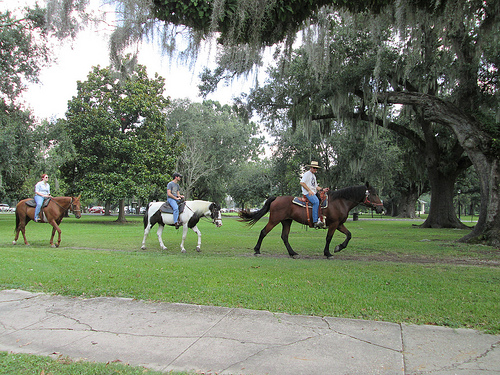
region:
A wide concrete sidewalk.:
[52, 288, 386, 368]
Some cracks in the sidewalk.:
[298, 302, 486, 369]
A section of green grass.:
[152, 248, 442, 308]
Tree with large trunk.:
[388, 46, 486, 230]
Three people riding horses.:
[11, 106, 413, 268]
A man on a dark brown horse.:
[247, 142, 389, 267]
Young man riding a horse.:
[140, 155, 223, 245]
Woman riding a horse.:
[10, 157, 87, 242]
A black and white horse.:
[127, 185, 237, 253]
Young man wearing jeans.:
[163, 169, 195, 249]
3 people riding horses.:
[11, 157, 388, 261]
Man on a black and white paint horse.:
[138, 169, 224, 254]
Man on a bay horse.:
[237, 158, 388, 260]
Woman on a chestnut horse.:
[11, 168, 84, 247]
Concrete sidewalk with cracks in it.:
[1, 287, 498, 374]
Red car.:
[87, 201, 108, 215]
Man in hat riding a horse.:
[237, 160, 387, 260]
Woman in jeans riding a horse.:
[12, 166, 85, 249]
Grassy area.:
[0, 212, 498, 332]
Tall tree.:
[58, 54, 179, 219]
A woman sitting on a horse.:
[26, 170, 56, 225]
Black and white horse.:
[137, 200, 223, 250]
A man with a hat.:
[296, 151, 334, 228]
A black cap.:
[163, 168, 187, 179]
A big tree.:
[74, 55, 166, 228]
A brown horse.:
[8, 192, 88, 248]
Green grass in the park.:
[236, 258, 358, 304]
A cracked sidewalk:
[153, 308, 243, 356]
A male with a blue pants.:
[158, 170, 189, 230]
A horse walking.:
[238, 185, 396, 257]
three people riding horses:
[10, 159, 385, 261]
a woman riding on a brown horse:
[12, 171, 84, 249]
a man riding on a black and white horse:
[140, 169, 225, 256]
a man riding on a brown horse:
[238, 158, 387, 260]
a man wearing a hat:
[297, 159, 330, 232]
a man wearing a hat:
[166, 170, 186, 229]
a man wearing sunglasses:
[299, 158, 326, 230]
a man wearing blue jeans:
[166, 170, 186, 229]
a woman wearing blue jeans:
[32, 173, 52, 222]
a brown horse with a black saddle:
[12, 193, 82, 248]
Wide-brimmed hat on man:
[302, 157, 322, 168]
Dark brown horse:
[240, 180, 385, 260]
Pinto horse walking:
[140, 196, 226, 251]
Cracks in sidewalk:
[27, 306, 405, 361]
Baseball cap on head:
[170, 172, 181, 177]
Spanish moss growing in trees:
[133, 6, 486, 138]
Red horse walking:
[7, 192, 83, 247]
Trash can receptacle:
[350, 211, 361, 218]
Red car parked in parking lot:
[86, 203, 102, 213]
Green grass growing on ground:
[2, 209, 494, 328]